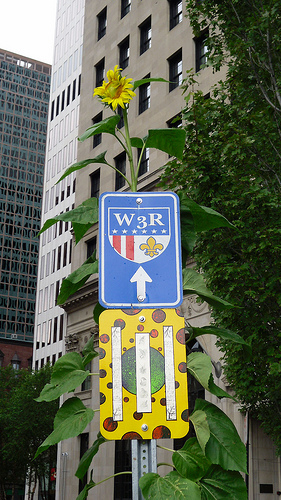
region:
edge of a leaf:
[195, 456, 227, 466]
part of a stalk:
[105, 466, 123, 482]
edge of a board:
[119, 422, 153, 457]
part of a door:
[117, 477, 123, 484]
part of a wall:
[94, 455, 108, 474]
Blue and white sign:
[95, 188, 190, 304]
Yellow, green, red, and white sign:
[91, 309, 200, 455]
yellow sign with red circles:
[91, 305, 195, 443]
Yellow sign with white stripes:
[85, 308, 199, 448]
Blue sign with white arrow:
[97, 194, 191, 305]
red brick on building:
[2, 343, 41, 434]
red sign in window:
[48, 465, 58, 485]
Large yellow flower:
[83, 67, 164, 196]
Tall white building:
[16, 3, 71, 493]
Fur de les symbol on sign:
[138, 233, 174, 265]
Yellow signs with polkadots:
[77, 303, 210, 459]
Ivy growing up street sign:
[48, 313, 278, 472]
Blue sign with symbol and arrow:
[78, 183, 195, 319]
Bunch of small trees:
[4, 337, 63, 495]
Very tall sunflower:
[30, 54, 240, 338]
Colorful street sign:
[77, 188, 212, 418]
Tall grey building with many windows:
[21, 0, 251, 243]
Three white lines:
[93, 309, 198, 450]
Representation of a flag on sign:
[102, 197, 177, 269]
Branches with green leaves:
[149, 39, 277, 249]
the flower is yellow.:
[81, 63, 142, 117]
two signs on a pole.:
[90, 188, 194, 498]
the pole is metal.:
[122, 434, 162, 498]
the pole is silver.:
[126, 433, 162, 497]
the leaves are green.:
[132, 319, 252, 498]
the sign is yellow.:
[95, 302, 192, 444]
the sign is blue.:
[95, 187, 188, 314]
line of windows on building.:
[45, 70, 88, 118]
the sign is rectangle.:
[93, 303, 199, 444]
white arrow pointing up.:
[125, 262, 154, 300]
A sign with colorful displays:
[95, 189, 195, 447]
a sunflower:
[91, 59, 183, 243]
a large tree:
[166, 28, 278, 390]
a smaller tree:
[1, 364, 52, 498]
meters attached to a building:
[59, 447, 78, 498]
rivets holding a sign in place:
[133, 196, 150, 304]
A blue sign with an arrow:
[99, 189, 180, 307]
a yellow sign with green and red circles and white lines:
[97, 307, 188, 438]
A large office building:
[55, 5, 276, 494]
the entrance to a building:
[239, 413, 279, 495]